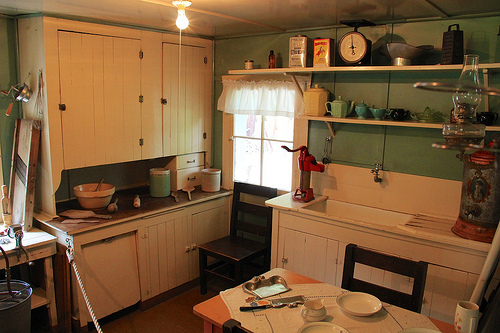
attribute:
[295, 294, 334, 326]
pitcher — white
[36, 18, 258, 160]
wooden cabinets — white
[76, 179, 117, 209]
bowl — large, beige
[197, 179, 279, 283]
chair — dark, brown, wooden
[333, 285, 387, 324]
plate — round, white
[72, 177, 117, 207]
bowl — mixing bowl, white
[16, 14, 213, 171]
cabinet — white, wooden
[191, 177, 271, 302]
wooden chair —  black,  wooden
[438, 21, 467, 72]
grater — rusty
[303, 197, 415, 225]
sink — long, deep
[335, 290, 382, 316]
plate — on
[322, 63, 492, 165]
walls — green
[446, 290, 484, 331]
mug — white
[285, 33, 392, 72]
items — miscellaneous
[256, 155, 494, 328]
sink — white, large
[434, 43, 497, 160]
lamp — antique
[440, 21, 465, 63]
cheese grater — metal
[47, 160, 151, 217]
bowl — large, ceramic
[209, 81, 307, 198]
curtains — white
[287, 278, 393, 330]
bowls — white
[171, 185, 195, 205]
spoons — brown, wooden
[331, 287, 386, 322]
plate — white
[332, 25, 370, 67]
clock — round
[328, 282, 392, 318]
bowl — empty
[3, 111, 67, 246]
mandoline — giant, metal, wood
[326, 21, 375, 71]
scale — large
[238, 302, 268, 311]
handle — black 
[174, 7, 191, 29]
light bulb — on